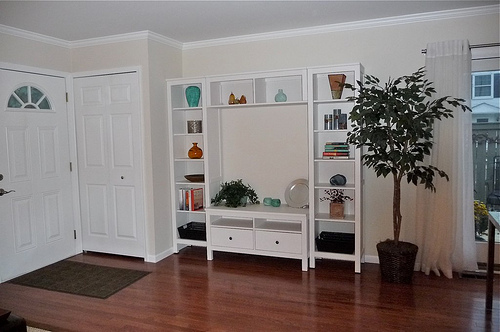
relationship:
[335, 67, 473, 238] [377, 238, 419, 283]
tree in basket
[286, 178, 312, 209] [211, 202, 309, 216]
plate on shelf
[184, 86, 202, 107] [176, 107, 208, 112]
vase on shelf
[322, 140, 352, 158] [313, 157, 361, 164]
books on shelf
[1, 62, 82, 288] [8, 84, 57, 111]
door with window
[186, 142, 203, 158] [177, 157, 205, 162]
vase on shelf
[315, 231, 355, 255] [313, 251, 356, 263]
basket on shelf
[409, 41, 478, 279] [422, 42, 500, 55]
curtains on rod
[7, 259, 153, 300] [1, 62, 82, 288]
rug by door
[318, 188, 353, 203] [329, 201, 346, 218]
plant in vase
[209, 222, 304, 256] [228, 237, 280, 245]
cabinets with knobs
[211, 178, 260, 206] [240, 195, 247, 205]
plant in pot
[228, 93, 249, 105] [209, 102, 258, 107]
pears on shelf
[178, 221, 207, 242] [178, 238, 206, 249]
basket on shelf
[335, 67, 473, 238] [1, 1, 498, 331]
tree in room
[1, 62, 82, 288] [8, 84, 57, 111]
door has window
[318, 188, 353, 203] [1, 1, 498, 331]
plant in room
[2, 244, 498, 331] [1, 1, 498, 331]
floors in room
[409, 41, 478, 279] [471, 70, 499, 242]
curtains on window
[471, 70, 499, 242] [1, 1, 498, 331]
window in room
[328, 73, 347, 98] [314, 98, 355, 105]
pot on shelf